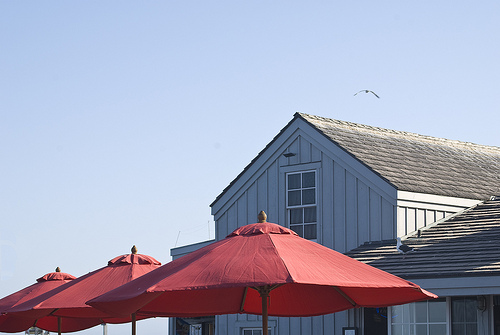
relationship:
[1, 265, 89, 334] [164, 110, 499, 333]
red umbrellas outside building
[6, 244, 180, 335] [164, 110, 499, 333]
red umbrellas outside building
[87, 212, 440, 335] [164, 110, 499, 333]
patio umbrella outside building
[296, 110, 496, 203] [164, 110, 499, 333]
roof on building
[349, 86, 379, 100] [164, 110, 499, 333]
bird above building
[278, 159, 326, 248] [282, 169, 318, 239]
frame on windows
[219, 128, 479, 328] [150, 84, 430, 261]
building has roof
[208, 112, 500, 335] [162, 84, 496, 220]
building has exterior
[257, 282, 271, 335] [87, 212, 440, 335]
pole under patio umbrella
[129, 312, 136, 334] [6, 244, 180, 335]
pole under red umbrellas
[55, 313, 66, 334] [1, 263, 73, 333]
pole under umbrella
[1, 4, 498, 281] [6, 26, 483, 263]
sky at daytime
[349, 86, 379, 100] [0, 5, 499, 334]
bird in sky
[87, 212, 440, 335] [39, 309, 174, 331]
patio umbrella with poles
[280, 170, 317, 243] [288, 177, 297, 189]
window with pane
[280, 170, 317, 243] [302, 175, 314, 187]
window with pane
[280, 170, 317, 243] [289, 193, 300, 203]
window with pane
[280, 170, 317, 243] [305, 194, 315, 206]
window with pane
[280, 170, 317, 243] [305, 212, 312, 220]
window with pane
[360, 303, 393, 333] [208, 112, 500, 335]
window on building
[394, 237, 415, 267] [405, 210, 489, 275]
seagull on roof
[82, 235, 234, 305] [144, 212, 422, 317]
panel in patio umbrella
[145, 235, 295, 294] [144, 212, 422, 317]
panel in patio umbrella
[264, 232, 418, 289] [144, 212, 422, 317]
panel in patio umbrella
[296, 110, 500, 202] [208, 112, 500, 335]
roof of building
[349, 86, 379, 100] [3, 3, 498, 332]
bird in air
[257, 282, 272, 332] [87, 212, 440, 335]
pole holding patio umbrella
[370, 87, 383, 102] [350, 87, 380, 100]
wing of bird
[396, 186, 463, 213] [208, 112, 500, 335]
fresher board of building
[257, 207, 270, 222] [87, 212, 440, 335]
tip of patio umbrella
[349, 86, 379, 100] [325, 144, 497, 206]
bird on roof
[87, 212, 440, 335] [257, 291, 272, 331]
patio umbrella on pole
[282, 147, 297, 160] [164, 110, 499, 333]
light on building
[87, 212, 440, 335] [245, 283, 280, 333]
patio umbrella on pole